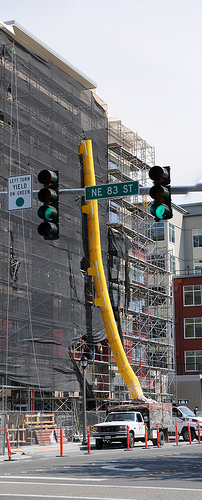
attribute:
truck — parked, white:
[90, 399, 173, 449]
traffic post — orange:
[51, 425, 71, 463]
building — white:
[138, 203, 201, 376]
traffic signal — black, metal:
[36, 164, 65, 243]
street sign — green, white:
[78, 182, 146, 206]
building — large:
[1, 24, 187, 425]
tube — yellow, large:
[75, 131, 180, 404]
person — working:
[0, 72, 23, 113]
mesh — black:
[1, 36, 130, 383]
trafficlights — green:
[25, 158, 181, 242]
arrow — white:
[97, 449, 161, 476]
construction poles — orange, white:
[2, 414, 201, 464]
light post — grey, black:
[73, 353, 101, 457]